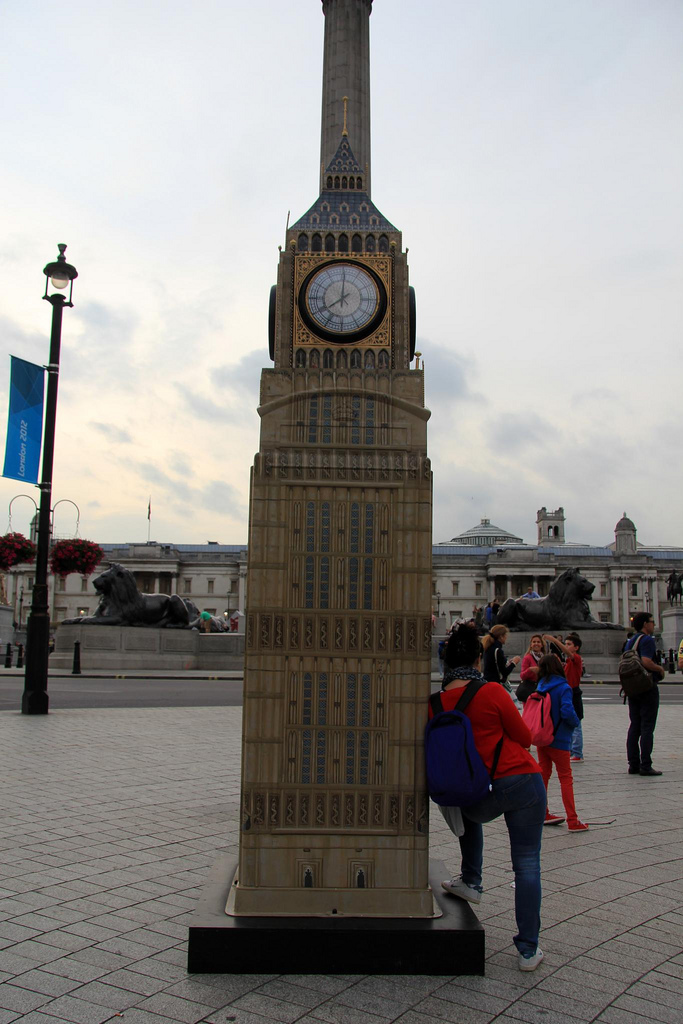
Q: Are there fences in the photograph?
A: No, there are no fences.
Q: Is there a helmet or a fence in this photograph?
A: No, there are no fences or helmets.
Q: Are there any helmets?
A: No, there are no helmets.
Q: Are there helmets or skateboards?
A: No, there are no helmets or skateboards.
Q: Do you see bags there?
A: Yes, there is a bag.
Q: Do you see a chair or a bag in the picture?
A: Yes, there is a bag.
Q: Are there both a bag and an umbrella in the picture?
A: No, there is a bag but no umbrellas.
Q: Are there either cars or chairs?
A: No, there are no chairs or cars.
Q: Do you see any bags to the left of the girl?
A: Yes, there is a bag to the left of the girl.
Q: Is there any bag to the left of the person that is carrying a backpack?
A: Yes, there is a bag to the left of the girl.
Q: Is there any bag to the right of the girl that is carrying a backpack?
A: No, the bag is to the left of the girl.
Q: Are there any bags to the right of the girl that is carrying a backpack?
A: No, the bag is to the left of the girl.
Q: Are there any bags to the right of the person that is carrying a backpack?
A: No, the bag is to the left of the girl.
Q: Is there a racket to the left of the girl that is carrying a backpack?
A: No, there is a bag to the left of the girl.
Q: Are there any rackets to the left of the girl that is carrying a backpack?
A: No, there is a bag to the left of the girl.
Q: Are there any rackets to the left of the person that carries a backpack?
A: No, there is a bag to the left of the girl.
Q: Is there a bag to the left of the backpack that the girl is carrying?
A: Yes, there is a bag to the left of the backpack.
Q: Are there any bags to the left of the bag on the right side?
A: Yes, there is a bag to the left of the backpack.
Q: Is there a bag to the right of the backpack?
A: No, the bag is to the left of the backpack.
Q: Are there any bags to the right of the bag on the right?
A: No, the bag is to the left of the backpack.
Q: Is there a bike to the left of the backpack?
A: No, there is a bag to the left of the backpack.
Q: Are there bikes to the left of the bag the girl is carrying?
A: No, there is a bag to the left of the backpack.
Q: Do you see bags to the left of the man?
A: Yes, there is a bag to the left of the man.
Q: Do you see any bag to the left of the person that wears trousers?
A: Yes, there is a bag to the left of the man.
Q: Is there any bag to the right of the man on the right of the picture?
A: No, the bag is to the left of the man.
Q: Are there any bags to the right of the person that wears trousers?
A: No, the bag is to the left of the man.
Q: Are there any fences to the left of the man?
A: No, there is a bag to the left of the man.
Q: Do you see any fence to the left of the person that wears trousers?
A: No, there is a bag to the left of the man.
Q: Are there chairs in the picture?
A: No, there are no chairs.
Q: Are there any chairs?
A: No, there are no chairs.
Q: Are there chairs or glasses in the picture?
A: No, there are no chairs or glasses.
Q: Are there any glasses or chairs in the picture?
A: No, there are no chairs or glasses.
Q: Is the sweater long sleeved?
A: Yes, the sweater is long sleeved.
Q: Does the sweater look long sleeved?
A: Yes, the sweater is long sleeved.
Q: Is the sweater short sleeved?
A: No, the sweater is long sleeved.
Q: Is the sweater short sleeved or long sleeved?
A: The sweater is long sleeved.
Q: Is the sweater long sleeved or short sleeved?
A: The sweater is long sleeved.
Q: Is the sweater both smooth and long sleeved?
A: Yes, the sweater is smooth and long sleeved.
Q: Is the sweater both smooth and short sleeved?
A: No, the sweater is smooth but long sleeved.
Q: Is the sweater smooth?
A: Yes, the sweater is smooth.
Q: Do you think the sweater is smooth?
A: Yes, the sweater is smooth.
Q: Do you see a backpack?
A: Yes, there is a backpack.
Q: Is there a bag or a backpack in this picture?
A: Yes, there is a backpack.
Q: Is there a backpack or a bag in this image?
A: Yes, there is a backpack.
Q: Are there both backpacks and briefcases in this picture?
A: No, there is a backpack but no briefcases.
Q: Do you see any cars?
A: No, there are no cars.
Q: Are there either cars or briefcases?
A: No, there are no cars or briefcases.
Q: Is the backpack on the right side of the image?
A: Yes, the backpack is on the right of the image.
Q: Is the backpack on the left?
A: No, the backpack is on the right of the image.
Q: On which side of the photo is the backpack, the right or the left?
A: The backpack is on the right of the image.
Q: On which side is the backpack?
A: The backpack is on the right of the image.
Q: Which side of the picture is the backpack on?
A: The backpack is on the right of the image.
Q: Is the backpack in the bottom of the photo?
A: Yes, the backpack is in the bottom of the image.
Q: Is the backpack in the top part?
A: No, the backpack is in the bottom of the image.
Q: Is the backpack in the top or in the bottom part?
A: The backpack is in the bottom of the image.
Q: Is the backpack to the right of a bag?
A: Yes, the backpack is to the right of a bag.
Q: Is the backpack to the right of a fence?
A: No, the backpack is to the right of a bag.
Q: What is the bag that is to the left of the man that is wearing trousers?
A: The bag is a backpack.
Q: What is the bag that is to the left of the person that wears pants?
A: The bag is a backpack.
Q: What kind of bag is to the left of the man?
A: The bag is a backpack.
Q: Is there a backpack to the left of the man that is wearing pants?
A: Yes, there is a backpack to the left of the man.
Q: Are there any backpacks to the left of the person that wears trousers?
A: Yes, there is a backpack to the left of the man.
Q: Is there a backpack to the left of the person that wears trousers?
A: Yes, there is a backpack to the left of the man.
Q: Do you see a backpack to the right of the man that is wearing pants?
A: No, the backpack is to the left of the man.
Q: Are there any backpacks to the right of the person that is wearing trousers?
A: No, the backpack is to the left of the man.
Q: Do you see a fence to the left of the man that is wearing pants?
A: No, there is a backpack to the left of the man.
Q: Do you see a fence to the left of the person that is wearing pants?
A: No, there is a backpack to the left of the man.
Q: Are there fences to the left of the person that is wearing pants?
A: No, there is a backpack to the left of the man.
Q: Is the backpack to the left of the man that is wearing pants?
A: Yes, the backpack is to the left of the man.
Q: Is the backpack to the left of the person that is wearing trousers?
A: Yes, the backpack is to the left of the man.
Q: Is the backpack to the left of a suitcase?
A: No, the backpack is to the left of the man.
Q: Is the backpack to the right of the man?
A: No, the backpack is to the left of the man.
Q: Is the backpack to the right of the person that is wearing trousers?
A: No, the backpack is to the left of the man.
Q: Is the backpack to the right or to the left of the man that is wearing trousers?
A: The backpack is to the left of the man.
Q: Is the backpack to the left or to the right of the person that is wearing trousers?
A: The backpack is to the left of the man.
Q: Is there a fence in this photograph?
A: No, there are no fences.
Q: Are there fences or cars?
A: No, there are no fences or cars.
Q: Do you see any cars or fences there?
A: No, there are no fences or cars.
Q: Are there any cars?
A: No, there are no cars.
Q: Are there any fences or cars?
A: No, there are no cars or fences.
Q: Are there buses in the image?
A: No, there are no buses.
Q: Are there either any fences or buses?
A: No, there are no buses or fences.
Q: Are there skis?
A: No, there are no skis.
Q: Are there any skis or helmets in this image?
A: No, there are no skis or helmets.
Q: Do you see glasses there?
A: No, there are no glasses.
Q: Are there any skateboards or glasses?
A: No, there are no glasses or skateboards.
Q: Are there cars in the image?
A: No, there are no cars.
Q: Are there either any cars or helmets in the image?
A: No, there are no cars or helmets.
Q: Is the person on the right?
A: Yes, the person is on the right of the image.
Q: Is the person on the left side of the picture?
A: No, the person is on the right of the image.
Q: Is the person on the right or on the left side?
A: The person is on the right of the image.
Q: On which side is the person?
A: The person is on the right of the image.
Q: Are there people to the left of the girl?
A: Yes, there is a person to the left of the girl.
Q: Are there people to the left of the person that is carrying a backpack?
A: Yes, there is a person to the left of the girl.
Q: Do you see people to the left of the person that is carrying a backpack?
A: Yes, there is a person to the left of the girl.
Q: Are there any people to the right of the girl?
A: No, the person is to the left of the girl.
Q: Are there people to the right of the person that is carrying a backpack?
A: No, the person is to the left of the girl.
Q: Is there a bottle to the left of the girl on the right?
A: No, there is a person to the left of the girl.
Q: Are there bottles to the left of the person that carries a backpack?
A: No, there is a person to the left of the girl.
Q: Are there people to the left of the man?
A: Yes, there is a person to the left of the man.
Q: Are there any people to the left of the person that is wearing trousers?
A: Yes, there is a person to the left of the man.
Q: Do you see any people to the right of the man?
A: No, the person is to the left of the man.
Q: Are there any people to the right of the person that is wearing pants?
A: No, the person is to the left of the man.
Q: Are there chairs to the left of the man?
A: No, there is a person to the left of the man.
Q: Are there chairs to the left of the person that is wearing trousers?
A: No, there is a person to the left of the man.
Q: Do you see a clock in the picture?
A: Yes, there is a clock.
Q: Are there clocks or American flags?
A: Yes, there is a clock.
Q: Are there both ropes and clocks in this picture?
A: No, there is a clock but no ropes.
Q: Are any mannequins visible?
A: No, there are no mannequins.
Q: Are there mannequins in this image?
A: No, there are no mannequins.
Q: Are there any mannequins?
A: No, there are no mannequins.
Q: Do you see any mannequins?
A: No, there are no mannequins.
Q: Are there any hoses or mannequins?
A: No, there are no mannequins or hoses.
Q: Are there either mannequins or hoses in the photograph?
A: No, there are no mannequins or hoses.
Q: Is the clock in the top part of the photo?
A: Yes, the clock is in the top of the image.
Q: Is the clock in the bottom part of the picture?
A: No, the clock is in the top of the image.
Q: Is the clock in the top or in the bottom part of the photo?
A: The clock is in the top of the image.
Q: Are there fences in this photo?
A: No, there are no fences.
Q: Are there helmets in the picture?
A: No, there are no helmets.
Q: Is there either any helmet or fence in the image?
A: No, there are no helmets or fences.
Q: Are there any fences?
A: No, there are no fences.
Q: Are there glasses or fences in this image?
A: No, there are no fences or glasses.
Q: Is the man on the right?
A: Yes, the man is on the right of the image.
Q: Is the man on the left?
A: No, the man is on the right of the image.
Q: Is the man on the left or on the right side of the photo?
A: The man is on the right of the image.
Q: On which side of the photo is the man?
A: The man is on the right of the image.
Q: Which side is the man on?
A: The man is on the right of the image.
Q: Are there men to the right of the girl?
A: Yes, there is a man to the right of the girl.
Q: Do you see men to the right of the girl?
A: Yes, there is a man to the right of the girl.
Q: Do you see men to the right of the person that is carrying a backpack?
A: Yes, there is a man to the right of the girl.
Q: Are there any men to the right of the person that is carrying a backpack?
A: Yes, there is a man to the right of the girl.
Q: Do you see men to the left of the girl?
A: No, the man is to the right of the girl.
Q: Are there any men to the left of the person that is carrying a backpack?
A: No, the man is to the right of the girl.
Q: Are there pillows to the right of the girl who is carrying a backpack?
A: No, there is a man to the right of the girl.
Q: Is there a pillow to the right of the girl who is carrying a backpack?
A: No, there is a man to the right of the girl.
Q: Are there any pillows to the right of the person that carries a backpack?
A: No, there is a man to the right of the girl.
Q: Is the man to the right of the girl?
A: Yes, the man is to the right of the girl.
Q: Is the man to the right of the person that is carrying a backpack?
A: Yes, the man is to the right of the girl.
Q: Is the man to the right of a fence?
A: No, the man is to the right of the girl.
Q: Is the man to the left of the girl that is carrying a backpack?
A: No, the man is to the right of the girl.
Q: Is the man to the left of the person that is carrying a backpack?
A: No, the man is to the right of the girl.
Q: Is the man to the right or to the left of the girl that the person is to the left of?
A: The man is to the right of the girl.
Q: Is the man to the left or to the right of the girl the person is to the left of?
A: The man is to the right of the girl.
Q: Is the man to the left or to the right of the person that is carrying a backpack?
A: The man is to the right of the girl.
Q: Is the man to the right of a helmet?
A: No, the man is to the right of the bag.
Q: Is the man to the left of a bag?
A: No, the man is to the right of a bag.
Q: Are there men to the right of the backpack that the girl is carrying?
A: Yes, there is a man to the right of the backpack.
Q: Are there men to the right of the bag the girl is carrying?
A: Yes, there is a man to the right of the backpack.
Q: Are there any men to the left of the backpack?
A: No, the man is to the right of the backpack.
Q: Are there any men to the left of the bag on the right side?
A: No, the man is to the right of the backpack.